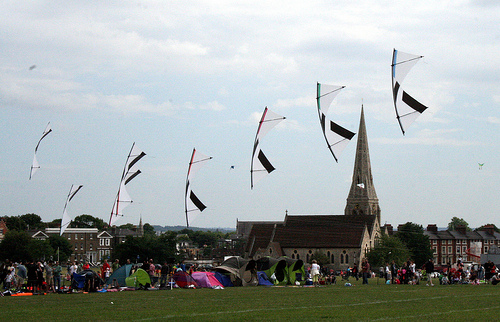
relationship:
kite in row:
[104, 120, 149, 235] [25, 46, 432, 239]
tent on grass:
[255, 253, 287, 286] [3, 274, 499, 319]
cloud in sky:
[91, 85, 231, 126] [1, 2, 498, 226]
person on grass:
[35, 259, 48, 289] [3, 274, 499, 319]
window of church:
[341, 249, 352, 267] [229, 208, 384, 275]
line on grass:
[155, 286, 497, 319] [3, 274, 499, 319]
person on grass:
[103, 267, 113, 280] [3, 274, 499, 319]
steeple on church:
[346, 92, 394, 221] [229, 208, 384, 275]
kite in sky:
[23, 117, 58, 185] [1, 2, 498, 226]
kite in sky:
[57, 173, 85, 241] [1, 2, 498, 226]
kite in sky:
[104, 120, 149, 235] [1, 2, 498, 226]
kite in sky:
[181, 136, 213, 230] [1, 2, 498, 226]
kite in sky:
[243, 94, 288, 189] [1, 2, 498, 226]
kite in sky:
[305, 68, 358, 163] [1, 2, 498, 226]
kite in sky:
[385, 43, 432, 136] [1, 2, 498, 226]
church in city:
[229, 208, 384, 275] [0, 211, 496, 276]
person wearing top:
[35, 259, 48, 289] [307, 260, 322, 281]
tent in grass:
[255, 253, 287, 286] [3, 274, 499, 319]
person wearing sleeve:
[98, 257, 113, 279] [99, 260, 111, 273]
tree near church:
[369, 229, 409, 273] [229, 208, 384, 275]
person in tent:
[139, 280, 149, 289] [126, 266, 153, 289]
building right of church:
[409, 220, 499, 271] [229, 208, 384, 275]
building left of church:
[7, 220, 151, 267] [229, 208, 384, 275]